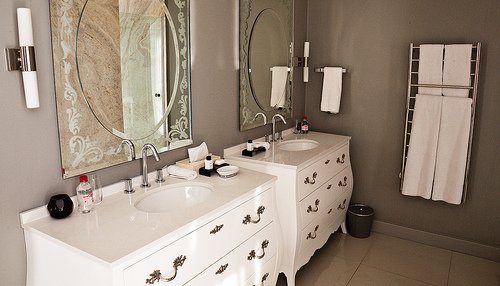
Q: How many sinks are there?
A: Two.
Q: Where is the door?
A: Reflection in mirror.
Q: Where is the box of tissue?
A: Sink.